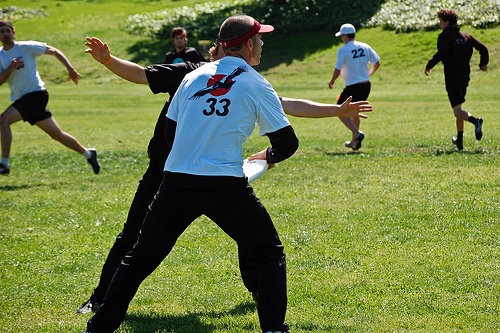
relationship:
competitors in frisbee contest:
[1, 8, 474, 167] [236, 149, 266, 179]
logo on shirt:
[191, 69, 252, 103] [167, 56, 284, 179]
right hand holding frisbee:
[251, 145, 281, 165] [235, 149, 274, 186]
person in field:
[323, 17, 380, 152] [10, 4, 482, 318]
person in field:
[5, 8, 83, 198] [10, 4, 482, 318]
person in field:
[424, 1, 490, 153] [10, 4, 482, 318]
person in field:
[153, 23, 217, 161] [10, 4, 482, 318]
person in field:
[174, 16, 299, 314] [10, 4, 482, 318]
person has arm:
[83, 18, 374, 322] [81, 31, 149, 88]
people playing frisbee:
[1, 8, 474, 167] [235, 149, 274, 186]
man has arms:
[83, 18, 374, 322] [87, 37, 370, 131]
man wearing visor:
[174, 16, 299, 314] [217, 21, 278, 45]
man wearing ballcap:
[323, 17, 380, 152] [334, 22, 356, 37]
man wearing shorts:
[5, 8, 83, 198] [11, 90, 61, 123]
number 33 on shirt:
[199, 92, 230, 120] [167, 56, 284, 179]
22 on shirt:
[349, 42, 366, 59] [329, 41, 380, 89]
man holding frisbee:
[174, 16, 299, 314] [235, 149, 274, 186]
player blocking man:
[83, 18, 374, 322] [174, 16, 299, 314]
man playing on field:
[424, 1, 490, 153] [10, 4, 482, 318]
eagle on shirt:
[191, 69, 252, 103] [167, 56, 284, 179]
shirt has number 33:
[167, 56, 284, 179] [199, 92, 230, 120]